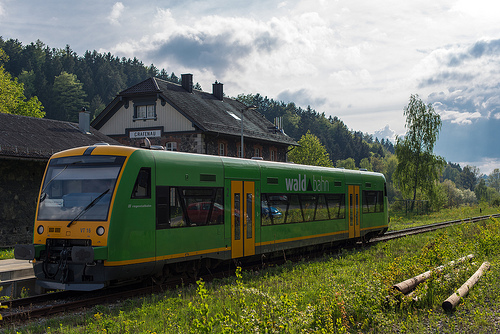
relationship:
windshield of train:
[60, 165, 117, 224] [143, 173, 359, 258]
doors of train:
[231, 188, 248, 255] [143, 173, 359, 258]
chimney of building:
[210, 73, 231, 102] [116, 82, 286, 148]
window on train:
[156, 193, 214, 227] [143, 173, 359, 258]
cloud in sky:
[150, 37, 255, 73] [476, 123, 488, 132]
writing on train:
[277, 172, 328, 192] [143, 173, 359, 258]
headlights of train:
[30, 222, 104, 235] [143, 173, 359, 258]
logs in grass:
[405, 265, 476, 299] [285, 276, 333, 296]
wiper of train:
[70, 189, 108, 228] [143, 173, 359, 258]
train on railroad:
[143, 173, 359, 258] [19, 291, 54, 318]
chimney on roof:
[210, 73, 231, 102] [213, 98, 250, 129]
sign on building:
[116, 119, 164, 138] [116, 82, 286, 148]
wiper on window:
[70, 189, 108, 228] [156, 193, 214, 227]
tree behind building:
[392, 96, 447, 202] [116, 82, 286, 148]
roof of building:
[213, 98, 250, 129] [116, 82, 286, 148]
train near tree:
[143, 173, 359, 258] [392, 96, 447, 202]